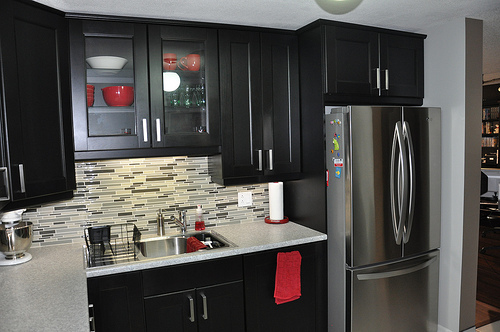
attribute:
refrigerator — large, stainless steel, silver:
[348, 105, 441, 331]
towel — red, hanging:
[274, 249, 301, 300]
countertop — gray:
[241, 228, 292, 238]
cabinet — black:
[154, 34, 212, 147]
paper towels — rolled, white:
[267, 182, 284, 217]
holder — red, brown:
[267, 215, 288, 226]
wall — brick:
[99, 159, 203, 204]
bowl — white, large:
[88, 51, 125, 72]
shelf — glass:
[88, 73, 135, 83]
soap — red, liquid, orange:
[196, 223, 204, 232]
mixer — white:
[4, 210, 28, 266]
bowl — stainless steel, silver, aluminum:
[2, 228, 27, 250]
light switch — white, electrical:
[240, 192, 253, 207]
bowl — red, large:
[106, 86, 132, 108]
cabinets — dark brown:
[12, 36, 298, 137]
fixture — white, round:
[310, 1, 360, 15]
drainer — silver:
[85, 227, 140, 262]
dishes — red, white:
[88, 54, 134, 107]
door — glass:
[77, 27, 146, 148]